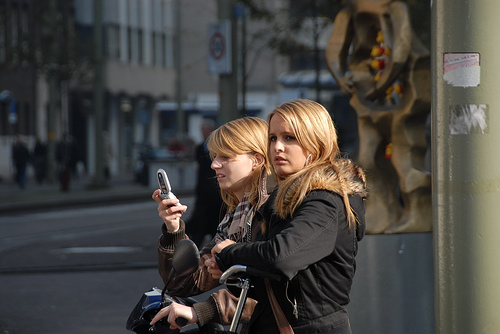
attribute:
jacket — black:
[192, 183, 372, 332]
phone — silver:
[163, 163, 193, 219]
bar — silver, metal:
[208, 259, 258, 331]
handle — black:
[242, 252, 289, 292]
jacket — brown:
[274, 193, 364, 332]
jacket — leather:
[163, 204, 267, 291]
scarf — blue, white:
[212, 189, 248, 237]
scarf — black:
[210, 192, 273, 248]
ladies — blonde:
[136, 115, 390, 330]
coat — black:
[266, 169, 377, 326]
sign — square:
[198, 0, 239, 90]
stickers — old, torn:
[433, 55, 485, 159]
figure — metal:
[324, 1, 458, 216]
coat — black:
[254, 128, 349, 332]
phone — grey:
[158, 153, 184, 224]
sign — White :
[205, 17, 241, 76]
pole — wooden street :
[214, 8, 259, 132]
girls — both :
[137, 102, 368, 330]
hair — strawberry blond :
[205, 100, 362, 220]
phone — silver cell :
[150, 166, 177, 200]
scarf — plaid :
[212, 185, 257, 242]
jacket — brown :
[244, 166, 380, 322]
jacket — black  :
[253, 170, 387, 321]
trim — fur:
[271, 161, 365, 198]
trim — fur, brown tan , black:
[275, 159, 371, 198]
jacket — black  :
[219, 154, 373, 324]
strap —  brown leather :
[252, 196, 302, 320]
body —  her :
[246, 170, 360, 316]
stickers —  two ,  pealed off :
[435, 44, 483, 132]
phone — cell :
[150, 158, 181, 226]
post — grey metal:
[425, 13, 485, 308]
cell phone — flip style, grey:
[145, 171, 185, 227]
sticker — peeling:
[428, 46, 488, 166]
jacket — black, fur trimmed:
[213, 144, 370, 318]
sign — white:
[198, 18, 237, 81]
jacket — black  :
[238, 163, 369, 323]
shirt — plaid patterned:
[206, 177, 276, 248]